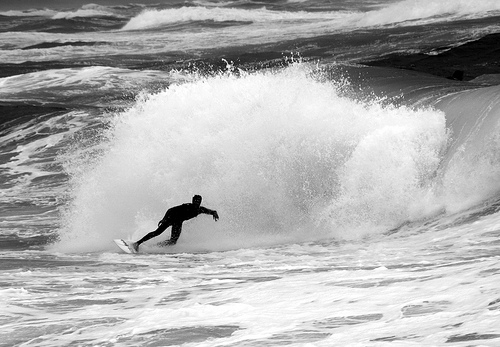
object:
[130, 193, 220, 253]
man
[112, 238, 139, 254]
surboard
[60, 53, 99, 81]
water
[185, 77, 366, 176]
waves